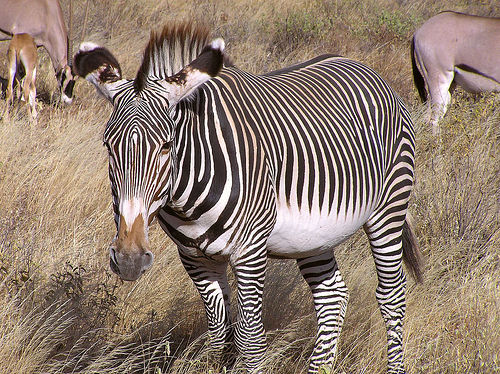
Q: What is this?
A: Zebra.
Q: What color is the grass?
A: Yellow.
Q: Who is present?
A: No one.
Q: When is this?
A: Daytime.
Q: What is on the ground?
A: Grass.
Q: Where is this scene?
A: At a zoo.